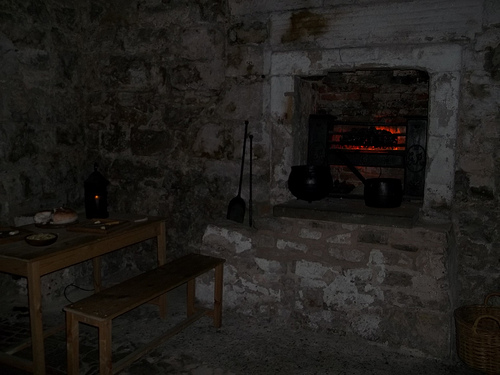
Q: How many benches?
A: 1.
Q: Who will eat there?
A: People.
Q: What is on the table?
A: Food.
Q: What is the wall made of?
A: Brick.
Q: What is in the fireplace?
A: Fire.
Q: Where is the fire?
A: In the fireplace.